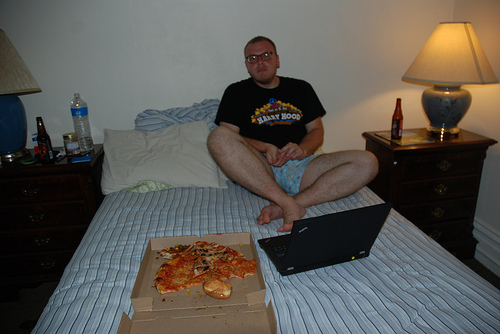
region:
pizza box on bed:
[115, 229, 280, 331]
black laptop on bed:
[258, 197, 394, 276]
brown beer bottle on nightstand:
[390, 95, 403, 145]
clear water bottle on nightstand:
[68, 91, 93, 148]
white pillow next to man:
[101, 120, 228, 195]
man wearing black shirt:
[215, 75, 324, 147]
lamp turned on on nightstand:
[402, 20, 498, 135]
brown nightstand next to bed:
[361, 125, 498, 260]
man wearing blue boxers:
[265, 150, 318, 194]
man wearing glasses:
[246, 51, 278, 66]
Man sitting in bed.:
[200, 28, 392, 237]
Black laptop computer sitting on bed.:
[251, 201, 399, 276]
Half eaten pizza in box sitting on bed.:
[113, 213, 280, 331]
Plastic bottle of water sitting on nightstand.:
[61, 90, 101, 153]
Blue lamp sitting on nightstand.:
[397, 9, 498, 144]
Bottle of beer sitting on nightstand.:
[381, 93, 408, 144]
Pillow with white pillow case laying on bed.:
[94, 117, 226, 210]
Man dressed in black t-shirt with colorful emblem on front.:
[211, 73, 336, 166]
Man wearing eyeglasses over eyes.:
[238, 47, 279, 66]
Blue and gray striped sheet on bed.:
[379, 249, 479, 332]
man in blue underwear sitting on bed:
[122, 21, 375, 216]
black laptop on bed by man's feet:
[261, 185, 393, 275]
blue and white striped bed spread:
[334, 258, 455, 311]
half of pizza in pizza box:
[121, 216, 278, 318]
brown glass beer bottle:
[381, 85, 408, 150]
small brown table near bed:
[370, 119, 488, 274]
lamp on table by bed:
[400, 12, 492, 148]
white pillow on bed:
[91, 113, 222, 200]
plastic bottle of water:
[70, 81, 107, 158]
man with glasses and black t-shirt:
[203, 24, 321, 139]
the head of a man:
[241, 32, 283, 84]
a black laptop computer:
[253, 200, 395, 278]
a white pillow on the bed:
[98, 117, 230, 194]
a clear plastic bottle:
[68, 89, 97, 154]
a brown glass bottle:
[386, 95, 406, 142]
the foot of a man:
[273, 195, 307, 234]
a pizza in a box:
[148, 239, 257, 300]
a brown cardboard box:
[114, 229, 277, 332]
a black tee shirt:
[216, 75, 327, 150]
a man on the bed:
[204, 32, 384, 237]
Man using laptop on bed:
[198, 20, 408, 278]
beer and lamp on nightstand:
[356, 3, 493, 205]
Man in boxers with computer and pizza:
[100, 5, 446, 323]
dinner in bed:
[101, 191, 299, 321]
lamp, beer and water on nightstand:
[1, 20, 144, 230]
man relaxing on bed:
[85, 16, 428, 323]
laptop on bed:
[252, 200, 402, 285]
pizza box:
[130, 230, 245, 325]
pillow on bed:
[98, 90, 218, 200]